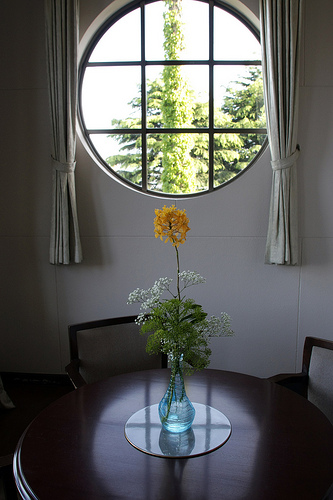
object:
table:
[12, 368, 333, 499]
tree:
[162, 1, 191, 196]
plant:
[138, 298, 212, 380]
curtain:
[257, 1, 303, 266]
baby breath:
[125, 268, 235, 372]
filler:
[139, 300, 211, 377]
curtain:
[43, 0, 84, 265]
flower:
[152, 205, 191, 424]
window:
[77, 0, 270, 198]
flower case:
[157, 352, 196, 434]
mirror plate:
[124, 401, 232, 458]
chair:
[64, 311, 168, 460]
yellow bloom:
[152, 203, 192, 248]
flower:
[153, 270, 174, 294]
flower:
[209, 309, 235, 335]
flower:
[125, 283, 151, 306]